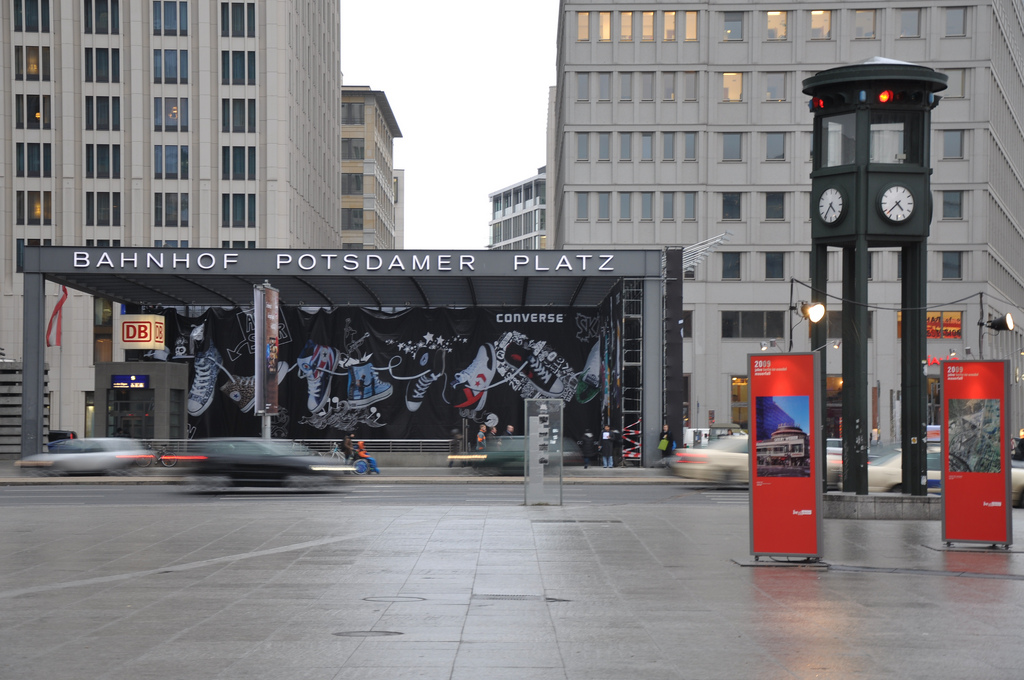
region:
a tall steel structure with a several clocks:
[792, 41, 957, 513]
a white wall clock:
[872, 179, 920, 227]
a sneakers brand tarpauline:
[280, 298, 604, 431]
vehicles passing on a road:
[6, 435, 354, 560]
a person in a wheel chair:
[337, 430, 398, 485]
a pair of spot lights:
[776, 272, 1023, 389]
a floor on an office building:
[546, 4, 1022, 77]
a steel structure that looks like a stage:
[19, 239, 705, 475]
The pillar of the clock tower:
[844, 313, 868, 415]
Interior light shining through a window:
[730, 73, 740, 99]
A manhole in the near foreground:
[346, 628, 386, 635]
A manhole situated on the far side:
[373, 594, 424, 602]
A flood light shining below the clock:
[808, 307, 824, 320]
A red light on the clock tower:
[881, 89, 891, 102]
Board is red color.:
[735, 330, 1015, 591]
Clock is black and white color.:
[793, 170, 921, 240]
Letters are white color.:
[51, 239, 624, 282]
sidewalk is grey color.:
[48, 523, 742, 656]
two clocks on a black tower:
[797, 54, 937, 507]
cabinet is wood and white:
[216, 43, 256, 86]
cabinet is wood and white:
[725, 309, 790, 336]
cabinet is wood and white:
[720, 248, 741, 283]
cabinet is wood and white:
[767, 243, 788, 279]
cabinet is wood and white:
[943, 248, 966, 280]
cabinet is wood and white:
[944, 191, 970, 226]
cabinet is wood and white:
[940, 129, 966, 168]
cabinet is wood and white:
[934, 68, 969, 104]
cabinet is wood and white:
[940, 3, 969, 38]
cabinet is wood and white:
[887, 3, 922, 41]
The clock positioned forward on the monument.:
[877, 190, 913, 222]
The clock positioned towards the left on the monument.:
[815, 186, 847, 225]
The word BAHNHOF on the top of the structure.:
[53, 239, 241, 266]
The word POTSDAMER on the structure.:
[271, 243, 486, 275]